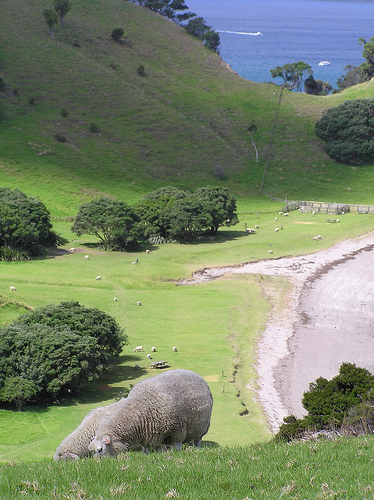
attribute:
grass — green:
[5, 449, 362, 493]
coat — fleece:
[123, 390, 200, 437]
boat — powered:
[254, 29, 268, 38]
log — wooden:
[248, 137, 264, 165]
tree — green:
[4, 179, 61, 262]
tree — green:
[69, 194, 158, 252]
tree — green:
[159, 193, 213, 242]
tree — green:
[191, 183, 243, 229]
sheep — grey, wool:
[87, 364, 217, 459]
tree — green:
[285, 363, 371, 441]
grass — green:
[216, 447, 356, 488]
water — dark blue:
[220, 3, 367, 84]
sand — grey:
[285, 256, 363, 392]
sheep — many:
[2, 208, 351, 307]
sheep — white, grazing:
[169, 344, 180, 353]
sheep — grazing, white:
[85, 366, 220, 468]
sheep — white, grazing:
[51, 399, 123, 464]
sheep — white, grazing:
[82, 252, 94, 262]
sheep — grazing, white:
[144, 246, 152, 256]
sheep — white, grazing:
[93, 272, 106, 284]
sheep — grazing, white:
[8, 282, 20, 292]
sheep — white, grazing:
[93, 272, 103, 282]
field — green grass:
[6, 211, 350, 283]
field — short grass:
[3, 215, 368, 284]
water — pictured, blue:
[161, 0, 373, 91]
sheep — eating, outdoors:
[54, 363, 218, 465]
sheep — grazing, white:
[67, 244, 77, 256]